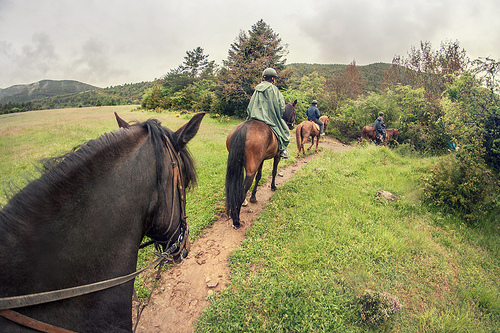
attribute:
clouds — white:
[75, 42, 125, 80]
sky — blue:
[18, 2, 233, 42]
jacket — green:
[244, 81, 289, 150]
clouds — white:
[307, 5, 409, 59]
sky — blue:
[83, 36, 166, 68]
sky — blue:
[5, 6, 498, 102]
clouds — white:
[369, 19, 387, 28]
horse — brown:
[216, 112, 388, 265]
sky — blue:
[320, 14, 385, 64]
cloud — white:
[1, 30, 134, 96]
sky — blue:
[0, 0, 500, 95]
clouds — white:
[326, 12, 413, 43]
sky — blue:
[130, 12, 197, 37]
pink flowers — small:
[346, 287, 408, 331]